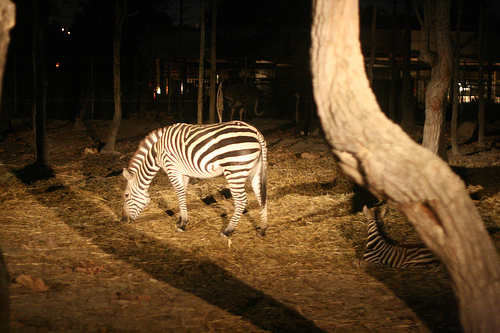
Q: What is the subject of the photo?
A: Animals.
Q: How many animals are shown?
A: Two.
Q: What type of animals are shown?
A: Zebras.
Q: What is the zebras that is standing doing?
A: Eating.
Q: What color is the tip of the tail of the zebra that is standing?
A: Black.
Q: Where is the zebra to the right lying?
A: On the ground.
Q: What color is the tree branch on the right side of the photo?
A: Brown.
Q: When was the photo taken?
A: Night.